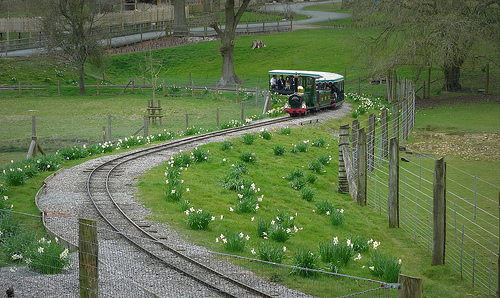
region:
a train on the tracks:
[227, 29, 407, 186]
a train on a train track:
[239, 57, 386, 210]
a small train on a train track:
[222, 57, 395, 219]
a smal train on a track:
[265, 26, 350, 198]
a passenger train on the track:
[274, 58, 390, 188]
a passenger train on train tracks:
[249, 48, 416, 225]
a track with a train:
[260, 39, 340, 161]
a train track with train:
[239, 48, 359, 161]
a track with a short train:
[264, 52, 357, 154]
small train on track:
[257, 59, 367, 140]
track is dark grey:
[84, 184, 237, 292]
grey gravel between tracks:
[98, 211, 224, 295]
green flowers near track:
[156, 105, 381, 292]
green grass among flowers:
[188, 153, 381, 291]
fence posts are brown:
[337, 70, 469, 265]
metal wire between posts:
[355, 90, 487, 280]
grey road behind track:
[1, 2, 333, 61]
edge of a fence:
[383, 172, 385, 178]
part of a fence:
[273, 255, 275, 260]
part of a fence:
[386, 185, 388, 209]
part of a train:
[298, 90, 299, 96]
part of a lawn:
[266, 213, 291, 263]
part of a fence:
[351, 112, 360, 139]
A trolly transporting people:
[262, 65, 350, 107]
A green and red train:
[255, 55, 352, 117]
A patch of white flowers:
[255, 203, 310, 238]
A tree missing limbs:
[210, 0, 247, 92]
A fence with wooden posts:
[360, 120, 456, 266]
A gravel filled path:
[57, 182, 82, 212]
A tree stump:
[245, 36, 277, 55]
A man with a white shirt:
[265, 74, 277, 89]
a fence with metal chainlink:
[0, 235, 131, 278]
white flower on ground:
[331, 226, 346, 253]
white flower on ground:
[339, 231, 364, 264]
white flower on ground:
[364, 238, 387, 256]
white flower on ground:
[275, 237, 295, 264]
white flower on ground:
[244, 244, 271, 265]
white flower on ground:
[236, 227, 246, 249]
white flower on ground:
[208, 225, 226, 248]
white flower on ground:
[181, 202, 196, 222]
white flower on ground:
[196, 191, 228, 228]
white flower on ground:
[244, 178, 263, 203]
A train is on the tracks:
[245, 57, 355, 128]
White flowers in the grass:
[0, 97, 405, 278]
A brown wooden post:
[380, 125, 410, 233]